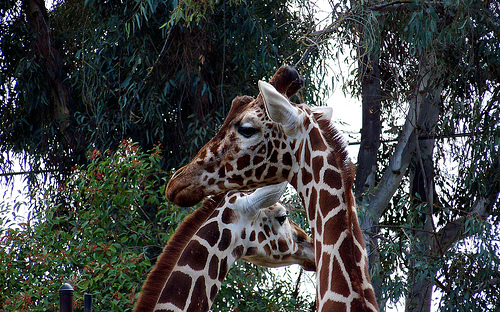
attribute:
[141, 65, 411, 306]
giraffe — elegant, tall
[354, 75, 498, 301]
trunk — scratchy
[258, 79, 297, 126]
ear — white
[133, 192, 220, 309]
mane — brown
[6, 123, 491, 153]
wire — thick, taut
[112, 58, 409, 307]
giraffe — younger, smaller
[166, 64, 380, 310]
giraffes — friendly, protective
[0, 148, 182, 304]
bush — blooming, pretty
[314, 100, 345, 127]
ear — white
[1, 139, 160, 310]
bush — small, wild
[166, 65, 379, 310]
giraffee — big, sensitive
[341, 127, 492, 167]
powerline — coated, thick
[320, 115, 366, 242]
mane — brown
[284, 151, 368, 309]
spots — pretty, contrast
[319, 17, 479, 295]
tree — gray, branching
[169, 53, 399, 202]
giraffe — larger, taller, older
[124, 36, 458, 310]
giraffe — brown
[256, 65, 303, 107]
giraffe horns — high, mighty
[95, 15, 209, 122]
leaves — glistening, healthy, tousled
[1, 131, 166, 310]
flowers — small, sweet, pretty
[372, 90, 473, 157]
wire — black, taut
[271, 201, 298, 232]
eye — brown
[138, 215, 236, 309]
neck — long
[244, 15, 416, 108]
sky — bright, daytime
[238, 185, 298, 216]
ear — white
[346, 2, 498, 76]
leaves — dark, heavy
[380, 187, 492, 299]
branch — white, long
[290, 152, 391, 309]
giraffe's neck — long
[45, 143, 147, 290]
leafy tree — orange, green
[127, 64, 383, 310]
two giraffes — brown, cream, pretty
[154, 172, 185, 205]
mouth — moist, large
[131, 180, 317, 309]
giraffe —  brown, white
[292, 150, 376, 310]
neck — long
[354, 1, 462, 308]
trees — mature, deciduous, untrimmed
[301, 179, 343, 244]
giraffe — statuesque, patient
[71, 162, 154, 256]
leaves — brittle, dry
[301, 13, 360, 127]
sky — heavenly, afternoon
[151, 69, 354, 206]
head — white, brown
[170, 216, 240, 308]
spots —  brown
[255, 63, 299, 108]
horn — brown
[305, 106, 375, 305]
mane — furry, brown